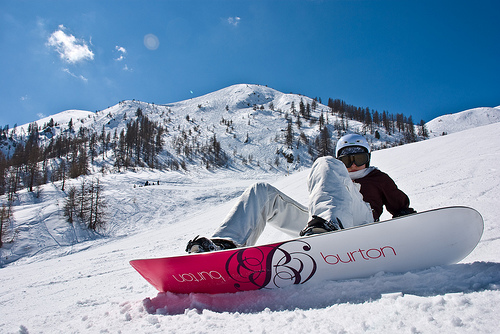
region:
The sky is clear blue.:
[1, 1, 495, 80]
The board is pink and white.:
[126, 210, 467, 292]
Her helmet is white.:
[333, 127, 374, 157]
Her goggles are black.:
[331, 145, 381, 167]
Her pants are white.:
[194, 166, 365, 234]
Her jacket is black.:
[340, 170, 410, 224]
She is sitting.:
[128, 138, 459, 276]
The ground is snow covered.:
[20, 135, 492, 324]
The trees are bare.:
[8, 117, 160, 227]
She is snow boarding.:
[38, 84, 492, 329]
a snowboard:
[130, 243, 475, 294]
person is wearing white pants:
[242, 190, 291, 215]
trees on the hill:
[58, 177, 128, 226]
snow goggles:
[342, 150, 372, 167]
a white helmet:
[336, 135, 366, 145]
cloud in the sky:
[52, 22, 99, 72]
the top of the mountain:
[223, 80, 273, 105]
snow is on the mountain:
[210, 88, 242, 109]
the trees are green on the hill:
[320, 93, 370, 117]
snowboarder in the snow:
[113, 120, 495, 297]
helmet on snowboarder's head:
[338, 127, 383, 182]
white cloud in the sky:
[43, 32, 99, 67]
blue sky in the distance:
[246, 34, 471, 81]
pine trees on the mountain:
[330, 96, 415, 141]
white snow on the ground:
[424, 146, 486, 188]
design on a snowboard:
[226, 245, 316, 291]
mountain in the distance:
[121, 80, 408, 156]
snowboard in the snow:
[129, 197, 488, 312]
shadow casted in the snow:
[145, 272, 430, 332]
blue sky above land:
[283, 7, 373, 68]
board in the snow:
[116, 206, 481, 322]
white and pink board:
[167, 236, 342, 291]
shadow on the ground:
[136, 291, 181, 316]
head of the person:
[330, 117, 382, 182]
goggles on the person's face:
[330, 140, 376, 177]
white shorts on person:
[230, 170, 300, 237]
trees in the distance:
[25, 131, 105, 187]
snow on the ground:
[110, 196, 175, 226]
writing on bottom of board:
[312, 232, 412, 287]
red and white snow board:
[126, 208, 479, 298]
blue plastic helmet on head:
[333, 133, 370, 176]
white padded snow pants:
[213, 158, 372, 253]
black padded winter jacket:
[345, 170, 418, 222]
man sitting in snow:
[166, 136, 415, 256]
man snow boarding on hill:
[136, 134, 486, 295]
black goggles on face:
[341, 151, 366, 168]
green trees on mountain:
[3, 109, 175, 187]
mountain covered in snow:
[171, 85, 332, 165]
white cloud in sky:
[45, 28, 95, 65]